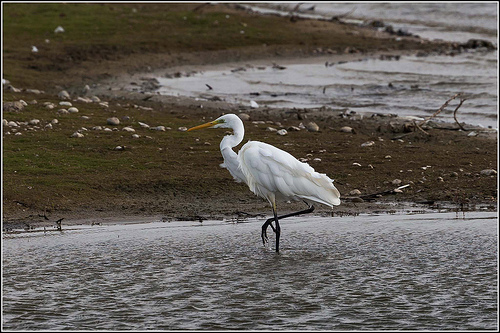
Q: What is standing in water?
A: White bird with orange beak.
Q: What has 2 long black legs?
A: White bird.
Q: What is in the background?
A: Patch of green grass.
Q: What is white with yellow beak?
A: The heron.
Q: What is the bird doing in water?
A: Wading.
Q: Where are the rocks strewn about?
A: The shore.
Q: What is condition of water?
A: Dark with ripples.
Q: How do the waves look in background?
A: Small waves.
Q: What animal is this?
A: Stork.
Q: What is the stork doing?
A: Standing.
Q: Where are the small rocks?
A: On the shore.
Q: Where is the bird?
A: In water.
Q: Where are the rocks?
A: Near water.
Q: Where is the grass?
A: Near water.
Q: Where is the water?
A: Near beach.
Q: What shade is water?
A: Brown.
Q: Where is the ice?
A: In water.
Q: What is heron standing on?
A: One leg.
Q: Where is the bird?
A: In lake.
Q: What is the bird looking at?
A: Other water birds.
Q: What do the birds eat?
A: Fish.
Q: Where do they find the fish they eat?
A: In the water.